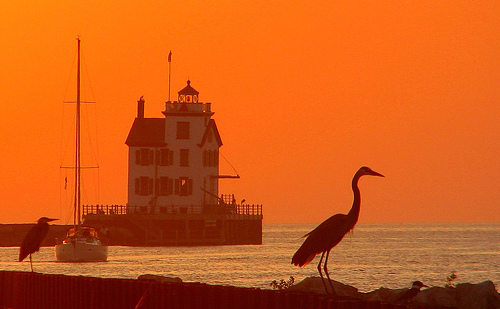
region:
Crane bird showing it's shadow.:
[291, 167, 389, 292]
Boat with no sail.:
[59, 44, 109, 262]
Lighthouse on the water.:
[108, 33, 260, 248]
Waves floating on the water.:
[371, 235, 496, 264]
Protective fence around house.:
[79, 205, 262, 222]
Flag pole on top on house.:
[163, 47, 177, 104]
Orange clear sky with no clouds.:
[243, 23, 480, 155]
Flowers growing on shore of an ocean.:
[262, 274, 301, 297]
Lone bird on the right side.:
[390, 276, 431, 304]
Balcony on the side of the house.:
[208, 168, 241, 184]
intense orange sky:
[0, 0, 496, 225]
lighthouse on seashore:
[123, 78, 220, 214]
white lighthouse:
[127, 77, 217, 222]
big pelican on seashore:
[290, 162, 385, 287]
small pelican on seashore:
[15, 215, 55, 267]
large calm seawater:
[0, 220, 495, 285]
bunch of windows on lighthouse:
[132, 145, 192, 195]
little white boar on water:
[56, 220, 106, 260]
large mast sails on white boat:
[75, 30, 85, 235]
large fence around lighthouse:
[80, 200, 262, 221]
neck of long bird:
[340, 178, 372, 206]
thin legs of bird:
[307, 255, 347, 296]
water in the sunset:
[367, 213, 463, 284]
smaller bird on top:
[10, 195, 69, 272]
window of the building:
[129, 140, 164, 172]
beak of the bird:
[368, 168, 385, 185]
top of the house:
[165, 61, 232, 116]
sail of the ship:
[63, 48, 119, 223]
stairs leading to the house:
[117, 203, 171, 241]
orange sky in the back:
[80, 48, 392, 98]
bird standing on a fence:
[290, 142, 391, 283]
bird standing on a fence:
[11, 209, 58, 274]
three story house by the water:
[114, 37, 272, 250]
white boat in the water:
[35, 25, 130, 277]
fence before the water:
[2, 264, 295, 306]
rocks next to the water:
[296, 273, 496, 303]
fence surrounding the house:
[81, 194, 266, 220]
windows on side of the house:
[136, 151, 199, 198]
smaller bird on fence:
[394, 277, 441, 301]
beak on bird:
[372, 162, 390, 184]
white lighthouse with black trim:
[123, 50, 242, 215]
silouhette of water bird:
[289, 157, 386, 299]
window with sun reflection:
[173, 173, 191, 195]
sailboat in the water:
[54, 30, 111, 267]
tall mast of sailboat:
[51, 31, 107, 226]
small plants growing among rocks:
[267, 270, 460, 292]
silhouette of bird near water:
[14, 213, 59, 271]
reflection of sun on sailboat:
[64, 223, 100, 238]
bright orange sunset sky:
[2, 0, 497, 224]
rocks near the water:
[276, 270, 498, 307]